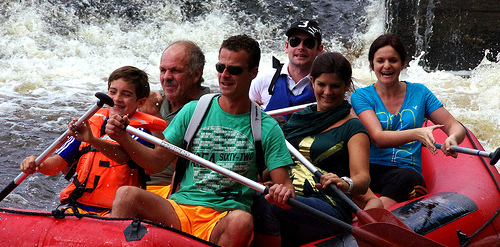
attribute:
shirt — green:
[279, 110, 371, 220]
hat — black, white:
[283, 15, 326, 49]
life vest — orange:
[71, 108, 163, 204]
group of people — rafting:
[71, 18, 465, 240]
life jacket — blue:
[267, 72, 318, 123]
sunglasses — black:
[211, 61, 259, 78]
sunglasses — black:
[287, 36, 323, 51]